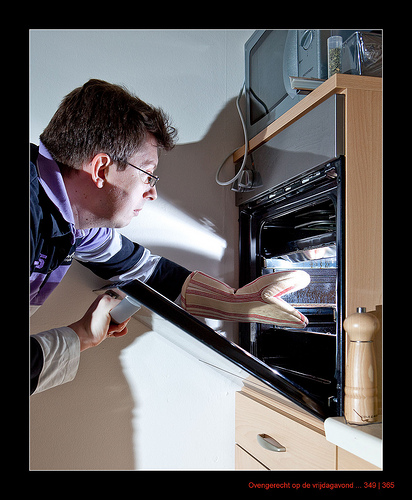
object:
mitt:
[185, 252, 325, 342]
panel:
[339, 72, 386, 431]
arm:
[78, 227, 228, 332]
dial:
[230, 166, 256, 188]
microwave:
[206, 57, 385, 341]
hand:
[78, 289, 130, 344]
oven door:
[88, 254, 332, 419]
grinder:
[345, 305, 372, 413]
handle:
[91, 293, 144, 328]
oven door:
[89, 273, 336, 424]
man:
[29, 79, 313, 405]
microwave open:
[230, 37, 334, 123]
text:
[248, 482, 393, 487]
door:
[230, 387, 345, 470]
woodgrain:
[268, 421, 314, 441]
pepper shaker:
[342, 306, 379, 423]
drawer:
[234, 391, 351, 467]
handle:
[254, 430, 286, 455]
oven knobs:
[231, 170, 251, 193]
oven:
[91, 93, 344, 422]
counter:
[308, 408, 396, 472]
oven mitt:
[179, 264, 314, 332]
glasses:
[111, 156, 158, 190]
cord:
[215, 79, 247, 186]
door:
[89, 277, 389, 486]